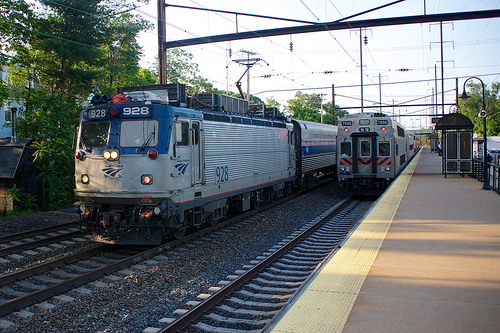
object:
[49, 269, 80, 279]
wooden board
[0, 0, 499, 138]
sky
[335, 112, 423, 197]
train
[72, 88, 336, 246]
light rail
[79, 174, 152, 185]
headllights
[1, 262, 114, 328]
board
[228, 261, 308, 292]
board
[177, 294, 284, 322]
board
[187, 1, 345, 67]
cloud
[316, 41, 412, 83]
cloud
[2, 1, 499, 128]
clouds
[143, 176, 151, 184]
headlight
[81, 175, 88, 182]
headlight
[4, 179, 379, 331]
tracks